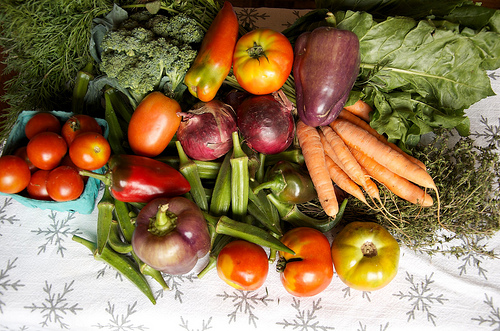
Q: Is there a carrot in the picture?
A: Yes, there is a carrot.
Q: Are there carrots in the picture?
A: Yes, there is a carrot.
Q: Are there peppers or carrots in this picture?
A: Yes, there is a carrot.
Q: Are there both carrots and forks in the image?
A: No, there is a carrot but no forks.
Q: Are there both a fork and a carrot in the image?
A: No, there is a carrot but no forks.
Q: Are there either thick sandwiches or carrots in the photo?
A: Yes, there is a thick carrot.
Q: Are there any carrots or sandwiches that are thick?
A: Yes, the carrot is thick.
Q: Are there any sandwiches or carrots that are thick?
A: Yes, the carrot is thick.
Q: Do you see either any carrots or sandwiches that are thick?
A: Yes, the carrot is thick.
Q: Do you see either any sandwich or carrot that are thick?
A: Yes, the carrot is thick.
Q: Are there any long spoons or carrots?
A: Yes, there is a long carrot.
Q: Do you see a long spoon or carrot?
A: Yes, there is a long carrot.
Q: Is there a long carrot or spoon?
A: Yes, there is a long carrot.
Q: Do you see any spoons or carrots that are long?
A: Yes, the carrot is long.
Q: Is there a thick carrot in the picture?
A: Yes, there is a thick carrot.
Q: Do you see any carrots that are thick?
A: Yes, there is a thick carrot.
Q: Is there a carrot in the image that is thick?
A: Yes, there is a carrot that is thick.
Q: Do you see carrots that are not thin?
A: Yes, there is a thick carrot.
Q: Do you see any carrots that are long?
A: Yes, there is a long carrot.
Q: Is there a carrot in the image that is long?
A: Yes, there is a carrot that is long.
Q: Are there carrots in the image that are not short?
A: Yes, there is a long carrot.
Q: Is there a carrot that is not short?
A: Yes, there is a long carrot.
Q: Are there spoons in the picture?
A: No, there are no spoons.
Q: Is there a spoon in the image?
A: No, there are no spoons.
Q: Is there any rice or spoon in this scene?
A: No, there are no spoons or rice.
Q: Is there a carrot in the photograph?
A: Yes, there is a carrot.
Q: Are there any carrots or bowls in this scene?
A: Yes, there is a carrot.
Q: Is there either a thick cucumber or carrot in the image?
A: Yes, there is a thick carrot.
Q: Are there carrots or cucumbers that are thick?
A: Yes, the carrot is thick.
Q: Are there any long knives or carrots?
A: Yes, there is a long carrot.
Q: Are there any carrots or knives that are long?
A: Yes, the carrot is long.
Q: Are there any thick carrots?
A: Yes, there is a thick carrot.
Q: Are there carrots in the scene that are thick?
A: Yes, there is a carrot that is thick.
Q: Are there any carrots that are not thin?
A: Yes, there is a thick carrot.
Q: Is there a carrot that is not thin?
A: Yes, there is a thick carrot.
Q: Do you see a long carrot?
A: Yes, there is a long carrot.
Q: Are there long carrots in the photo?
A: Yes, there is a long carrot.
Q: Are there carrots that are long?
A: Yes, there is a carrot that is long.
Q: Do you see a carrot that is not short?
A: Yes, there is a long carrot.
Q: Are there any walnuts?
A: No, there are no walnuts.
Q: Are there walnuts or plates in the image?
A: No, there are no walnuts or plates.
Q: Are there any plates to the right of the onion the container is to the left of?
A: No, there is a carrot to the right of the onion.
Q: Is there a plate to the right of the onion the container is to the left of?
A: No, there is a carrot to the right of the onion.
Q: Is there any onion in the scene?
A: Yes, there is an onion.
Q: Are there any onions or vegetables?
A: Yes, there is an onion.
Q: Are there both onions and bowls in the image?
A: No, there is an onion but no bowls.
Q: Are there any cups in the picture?
A: No, there are no cups.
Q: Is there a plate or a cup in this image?
A: No, there are no cups or plates.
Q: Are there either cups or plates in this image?
A: No, there are no cups or plates.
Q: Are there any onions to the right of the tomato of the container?
A: Yes, there is an onion to the right of the tomato.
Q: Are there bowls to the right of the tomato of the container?
A: No, there is an onion to the right of the tomato.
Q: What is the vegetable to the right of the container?
A: The vegetable is an onion.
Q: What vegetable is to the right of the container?
A: The vegetable is an onion.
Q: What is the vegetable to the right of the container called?
A: The vegetable is an onion.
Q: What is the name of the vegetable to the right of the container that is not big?
A: The vegetable is an onion.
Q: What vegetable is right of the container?
A: The vegetable is an onion.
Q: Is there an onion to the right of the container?
A: Yes, there is an onion to the right of the container.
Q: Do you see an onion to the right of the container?
A: Yes, there is an onion to the right of the container.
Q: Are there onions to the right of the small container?
A: Yes, there is an onion to the right of the container.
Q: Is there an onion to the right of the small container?
A: Yes, there is an onion to the right of the container.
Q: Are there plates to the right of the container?
A: No, there is an onion to the right of the container.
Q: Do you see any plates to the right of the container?
A: No, there is an onion to the right of the container.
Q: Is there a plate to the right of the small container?
A: No, there is an onion to the right of the container.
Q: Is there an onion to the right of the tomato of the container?
A: Yes, there is an onion to the right of the tomato.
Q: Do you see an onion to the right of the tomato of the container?
A: Yes, there is an onion to the right of the tomato.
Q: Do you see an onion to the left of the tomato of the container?
A: No, the onion is to the right of the tomato.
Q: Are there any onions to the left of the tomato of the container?
A: No, the onion is to the right of the tomato.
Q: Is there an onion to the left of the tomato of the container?
A: No, the onion is to the right of the tomato.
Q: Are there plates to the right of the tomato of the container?
A: No, there is an onion to the right of the tomato.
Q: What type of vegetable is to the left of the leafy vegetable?
A: The vegetable is an onion.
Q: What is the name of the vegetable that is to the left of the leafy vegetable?
A: The vegetable is an onion.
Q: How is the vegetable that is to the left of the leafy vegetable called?
A: The vegetable is an onion.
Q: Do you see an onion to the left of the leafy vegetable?
A: Yes, there is an onion to the left of the vegetable.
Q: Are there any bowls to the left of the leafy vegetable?
A: No, there is an onion to the left of the vegetable.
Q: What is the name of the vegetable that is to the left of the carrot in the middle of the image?
A: The vegetable is an onion.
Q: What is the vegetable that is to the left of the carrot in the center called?
A: The vegetable is an onion.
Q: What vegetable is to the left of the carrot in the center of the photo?
A: The vegetable is an onion.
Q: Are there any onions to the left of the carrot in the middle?
A: Yes, there is an onion to the left of the carrot.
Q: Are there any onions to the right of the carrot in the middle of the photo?
A: No, the onion is to the left of the carrot.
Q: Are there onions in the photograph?
A: Yes, there is an onion.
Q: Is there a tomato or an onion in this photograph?
A: Yes, there is an onion.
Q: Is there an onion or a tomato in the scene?
A: Yes, there is an onion.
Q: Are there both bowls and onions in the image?
A: No, there is an onion but no bowls.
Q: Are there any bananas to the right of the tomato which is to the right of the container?
A: No, there is an onion to the right of the tomato.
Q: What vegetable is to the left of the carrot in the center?
A: The vegetable is an onion.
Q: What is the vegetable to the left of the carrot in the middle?
A: The vegetable is an onion.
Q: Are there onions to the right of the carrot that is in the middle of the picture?
A: No, the onion is to the left of the carrot.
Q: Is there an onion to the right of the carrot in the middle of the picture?
A: No, the onion is to the left of the carrot.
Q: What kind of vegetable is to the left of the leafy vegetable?
A: The vegetable is an onion.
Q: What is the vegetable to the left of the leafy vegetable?
A: The vegetable is an onion.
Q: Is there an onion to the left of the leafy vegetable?
A: Yes, there is an onion to the left of the vegetable.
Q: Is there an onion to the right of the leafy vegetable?
A: No, the onion is to the left of the vegetable.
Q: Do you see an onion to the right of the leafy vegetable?
A: No, the onion is to the left of the vegetable.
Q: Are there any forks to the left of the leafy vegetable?
A: No, there is an onion to the left of the vegetable.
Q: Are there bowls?
A: No, there are no bowls.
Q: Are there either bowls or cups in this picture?
A: No, there are no bowls or cups.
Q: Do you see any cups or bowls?
A: No, there are no bowls or cups.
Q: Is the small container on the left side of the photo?
A: Yes, the container is on the left of the image.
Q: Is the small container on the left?
A: Yes, the container is on the left of the image.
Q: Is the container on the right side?
A: No, the container is on the left of the image.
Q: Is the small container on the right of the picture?
A: No, the container is on the left of the image.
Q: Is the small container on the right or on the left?
A: The container is on the left of the image.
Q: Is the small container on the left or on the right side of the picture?
A: The container is on the left of the image.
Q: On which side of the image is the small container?
A: The container is on the left of the image.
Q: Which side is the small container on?
A: The container is on the left of the image.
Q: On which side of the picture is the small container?
A: The container is on the left of the image.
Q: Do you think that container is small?
A: Yes, the container is small.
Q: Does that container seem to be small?
A: Yes, the container is small.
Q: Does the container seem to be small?
A: Yes, the container is small.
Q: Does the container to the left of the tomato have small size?
A: Yes, the container is small.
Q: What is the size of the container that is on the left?
A: The container is small.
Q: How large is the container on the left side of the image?
A: The container is small.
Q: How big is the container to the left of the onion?
A: The container is small.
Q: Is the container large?
A: No, the container is small.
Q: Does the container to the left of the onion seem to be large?
A: No, the container is small.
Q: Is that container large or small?
A: The container is small.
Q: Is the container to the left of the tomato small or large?
A: The container is small.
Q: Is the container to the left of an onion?
A: Yes, the container is to the left of an onion.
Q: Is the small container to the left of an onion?
A: Yes, the container is to the left of an onion.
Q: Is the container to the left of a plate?
A: No, the container is to the left of an onion.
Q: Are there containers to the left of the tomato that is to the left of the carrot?
A: Yes, there is a container to the left of the tomato.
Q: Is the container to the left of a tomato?
A: Yes, the container is to the left of a tomato.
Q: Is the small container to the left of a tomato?
A: Yes, the container is to the left of a tomato.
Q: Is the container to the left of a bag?
A: No, the container is to the left of a tomato.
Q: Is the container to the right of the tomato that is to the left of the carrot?
A: No, the container is to the left of the tomato.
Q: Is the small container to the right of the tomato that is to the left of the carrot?
A: No, the container is to the left of the tomato.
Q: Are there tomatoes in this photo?
A: Yes, there is a tomato.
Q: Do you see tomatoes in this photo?
A: Yes, there is a tomato.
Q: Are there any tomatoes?
A: Yes, there is a tomato.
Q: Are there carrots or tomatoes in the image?
A: Yes, there is a tomato.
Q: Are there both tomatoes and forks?
A: No, there is a tomato but no forks.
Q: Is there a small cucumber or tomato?
A: Yes, there is a small tomato.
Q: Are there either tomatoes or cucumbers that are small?
A: Yes, the tomato is small.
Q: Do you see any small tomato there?
A: Yes, there is a small tomato.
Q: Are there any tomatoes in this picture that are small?
A: Yes, there is a tomato that is small.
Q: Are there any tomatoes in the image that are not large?
A: Yes, there is a small tomato.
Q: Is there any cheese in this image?
A: No, there is no cheese.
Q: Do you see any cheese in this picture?
A: No, there is no cheese.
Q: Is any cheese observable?
A: No, there is no cheese.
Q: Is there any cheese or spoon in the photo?
A: No, there are no cheese or spoons.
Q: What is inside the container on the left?
A: The tomato is inside the container.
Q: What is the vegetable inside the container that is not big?
A: The vegetable is a tomato.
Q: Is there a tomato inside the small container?
A: Yes, there is a tomato inside the container.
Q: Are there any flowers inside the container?
A: No, there is a tomato inside the container.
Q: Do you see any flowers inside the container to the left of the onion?
A: No, there is a tomato inside the container.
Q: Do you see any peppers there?
A: Yes, there is a pepper.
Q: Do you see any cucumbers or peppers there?
A: Yes, there is a pepper.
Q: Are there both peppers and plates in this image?
A: No, there is a pepper but no plates.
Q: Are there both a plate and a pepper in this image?
A: No, there is a pepper but no plates.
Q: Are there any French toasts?
A: No, there are no French toasts.